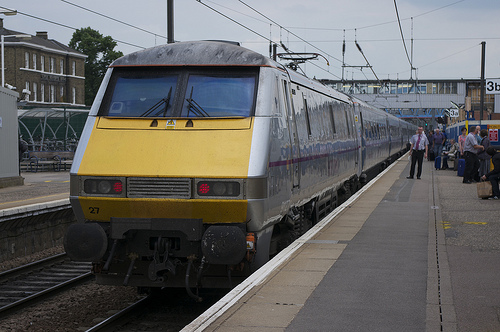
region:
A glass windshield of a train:
[77, 58, 288, 133]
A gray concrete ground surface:
[320, 231, 421, 327]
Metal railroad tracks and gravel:
[8, 256, 100, 330]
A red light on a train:
[191, 178, 215, 201]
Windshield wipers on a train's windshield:
[140, 80, 213, 126]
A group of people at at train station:
[402, 110, 499, 209]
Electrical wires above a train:
[219, 7, 430, 51]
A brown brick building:
[6, 11, 96, 108]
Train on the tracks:
[63, 38, 425, 293]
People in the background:
[406, 119, 499, 192]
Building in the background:
[310, 73, 489, 139]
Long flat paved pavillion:
[178, 149, 498, 330]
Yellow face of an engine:
[74, 114, 261, 228]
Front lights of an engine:
[78, 175, 245, 200]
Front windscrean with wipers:
[93, 63, 269, 125]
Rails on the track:
[0, 246, 205, 330]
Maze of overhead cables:
[2, 12, 477, 113]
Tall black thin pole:
[478, 37, 488, 152]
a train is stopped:
[65, 38, 419, 287]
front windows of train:
[102, 71, 254, 118]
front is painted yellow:
[78, 117, 251, 224]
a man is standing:
[407, 127, 426, 177]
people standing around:
[458, 123, 482, 181]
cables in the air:
[1, 0, 498, 78]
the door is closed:
[282, 75, 299, 187]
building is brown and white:
[0, 21, 85, 108]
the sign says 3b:
[485, 77, 499, 92]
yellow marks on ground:
[440, 218, 484, 230]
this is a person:
[408, 106, 431, 187]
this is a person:
[462, 122, 485, 181]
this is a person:
[430, 129, 451, 168]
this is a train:
[68, 20, 333, 282]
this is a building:
[5, 20, 80, 145]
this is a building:
[380, 75, 465, 115]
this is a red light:
[198, 182, 213, 193]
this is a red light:
[111, 179, 123, 196]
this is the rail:
[1, 250, 73, 320]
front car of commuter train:
[63, 31, 269, 293]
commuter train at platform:
[62, 37, 428, 284]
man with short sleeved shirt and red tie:
[403, 122, 435, 184]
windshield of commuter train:
[98, 63, 259, 121]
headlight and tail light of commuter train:
[69, 169, 248, 205]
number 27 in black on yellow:
[85, 202, 102, 219]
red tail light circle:
[197, 179, 212, 195]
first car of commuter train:
[65, 42, 366, 292]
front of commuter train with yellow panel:
[57, 37, 276, 291]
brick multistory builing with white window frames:
[1, 32, 89, 113]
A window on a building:
[23, 52, 28, 69]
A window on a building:
[32, 52, 37, 69]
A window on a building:
[39, 55, 44, 72]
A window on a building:
[51, 54, 56, 73]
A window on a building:
[60, 59, 65, 71]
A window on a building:
[32, 80, 39, 99]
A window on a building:
[39, 79, 45, 101]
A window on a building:
[49, 83, 54, 99]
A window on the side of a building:
[23, 54, 29, 67]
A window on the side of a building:
[33, 54, 38, 71]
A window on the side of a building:
[39, 56, 45, 71]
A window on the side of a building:
[50, 58, 55, 70]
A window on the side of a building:
[59, 60, 63, 74]